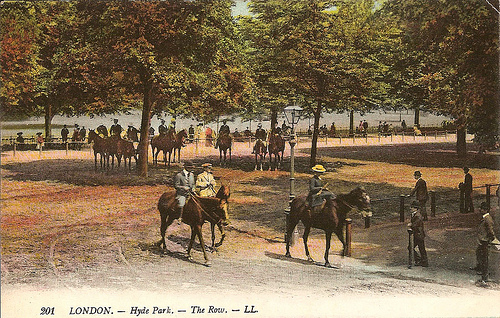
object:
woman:
[162, 149, 234, 223]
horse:
[163, 203, 235, 249]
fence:
[36, 130, 62, 141]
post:
[274, 97, 306, 172]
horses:
[169, 197, 331, 250]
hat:
[301, 164, 342, 202]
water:
[91, 106, 145, 116]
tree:
[143, 23, 204, 72]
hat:
[174, 158, 202, 172]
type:
[289, 192, 342, 223]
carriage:
[230, 174, 337, 249]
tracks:
[86, 235, 138, 273]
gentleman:
[97, 98, 178, 158]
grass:
[27, 169, 95, 233]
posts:
[424, 183, 444, 219]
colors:
[42, 28, 95, 85]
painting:
[27, 35, 367, 235]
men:
[143, 154, 223, 192]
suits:
[168, 166, 220, 186]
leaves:
[69, 22, 119, 64]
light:
[260, 99, 346, 195]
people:
[90, 117, 327, 191]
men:
[389, 168, 491, 203]